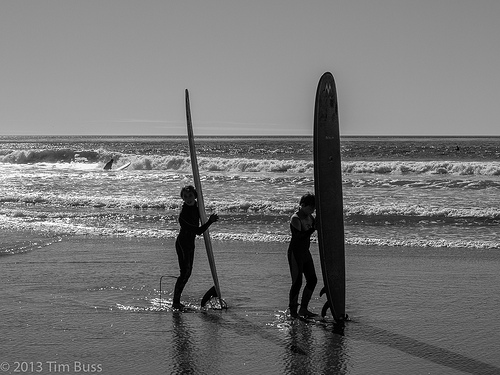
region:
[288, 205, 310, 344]
Person standing on beach.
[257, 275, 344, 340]
Person's feet in water.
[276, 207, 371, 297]
Person standing next to tall board.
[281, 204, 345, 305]
Person wearing wet suit.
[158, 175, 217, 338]
Person standing next to tall board.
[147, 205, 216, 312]
Person standing on beach.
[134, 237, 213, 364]
Person's feet in water.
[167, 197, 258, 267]
Person's arm in front of board.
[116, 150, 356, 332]
2 people standing on beach.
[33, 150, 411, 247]
Waves rolling in behind people.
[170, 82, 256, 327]
this is a white surfboard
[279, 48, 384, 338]
this is a black surfboard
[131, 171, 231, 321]
this is a young girl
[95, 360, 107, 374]
this is the letter s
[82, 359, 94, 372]
the gray letter u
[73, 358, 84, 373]
the gray letter b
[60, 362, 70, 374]
the gray letter m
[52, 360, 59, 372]
the gray letter i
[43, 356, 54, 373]
the gray letter t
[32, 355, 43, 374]
the gray number 3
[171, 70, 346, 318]
Two surfers with surfboards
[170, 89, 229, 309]
female surfer with a surfboard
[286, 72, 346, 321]
male surfer with a surfboard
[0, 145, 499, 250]
waves breaking on the shoreline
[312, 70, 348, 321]
a long, upright surfboard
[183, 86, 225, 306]
a long, upright surfboard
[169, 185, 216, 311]
a female surfer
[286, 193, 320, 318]
a male surfer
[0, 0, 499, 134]
the sky above the ocean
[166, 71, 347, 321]
Two surfers with boards on shore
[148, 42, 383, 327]
two surfers preparing to surf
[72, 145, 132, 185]
person surfing in ocean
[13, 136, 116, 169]
breaking wave in the ocean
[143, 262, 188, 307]
surfboard strap for surfer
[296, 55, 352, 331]
a tall dark surfboard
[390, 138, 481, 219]
waves in the ocean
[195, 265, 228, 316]
fin of a surfboard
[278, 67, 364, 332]
small female child surfer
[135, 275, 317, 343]
receeding water around the surfers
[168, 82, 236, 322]
light colored surfboard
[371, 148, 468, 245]
Ocean waves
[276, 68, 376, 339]
surfer with long board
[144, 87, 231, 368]
Female surfer with long board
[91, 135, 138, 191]
Surfer in the waves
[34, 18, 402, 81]
cloudless day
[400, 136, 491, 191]
surfer far out in the water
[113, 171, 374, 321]
Surfers posing with their boards.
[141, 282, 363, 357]
splashing in the water.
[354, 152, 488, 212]
ocean waves are rolling in.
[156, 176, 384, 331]
surfers dressed in wet suits.